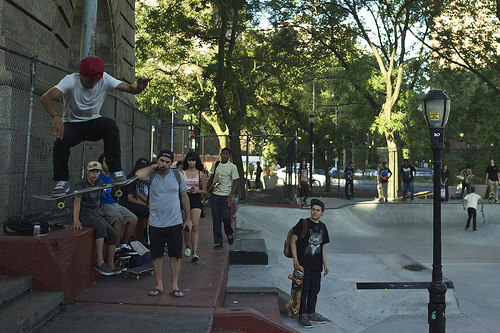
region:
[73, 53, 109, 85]
guy wearing red hat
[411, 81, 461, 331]
black street light pole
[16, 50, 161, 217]
guy jumping down steps on skateboard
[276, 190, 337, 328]
guy holding skate board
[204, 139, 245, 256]
guy walking down sidewalk with skateboard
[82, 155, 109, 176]
guy wearing tan hat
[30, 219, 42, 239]
can of soda pop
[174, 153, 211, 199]
girl wearing pink shirt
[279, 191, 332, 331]
guy wearing brown back pack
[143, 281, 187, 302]
guy wearing brown flip flops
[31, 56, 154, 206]
a skateboarder in air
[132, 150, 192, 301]
a man standing on sidewalk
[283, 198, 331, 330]
a man standing on sidewalk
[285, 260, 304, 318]
a standing skateboard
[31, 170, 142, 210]
a green and black skateboard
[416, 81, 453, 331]
a black street light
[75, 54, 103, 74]
a man's red hat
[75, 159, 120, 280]
a young man sitting on wall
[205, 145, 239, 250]
a pedestrian walking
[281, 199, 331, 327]
a young man with backpack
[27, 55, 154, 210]
A skateboarder in the air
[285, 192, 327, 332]
A man stands with a skateboarder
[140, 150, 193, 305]
A man with a gray t shirt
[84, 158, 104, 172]
The hat is yellow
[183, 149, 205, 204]
A girl is wearing a tank top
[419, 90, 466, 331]
The lamp post is black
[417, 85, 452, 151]
The lamp is off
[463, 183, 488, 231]
A person has a white shirt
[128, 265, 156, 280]
A skateboard on the ground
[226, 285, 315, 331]
The stairs are red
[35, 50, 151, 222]
a young man on a skateboard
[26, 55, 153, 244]
man and skateboard in the air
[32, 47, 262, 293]
group of people watching the skateboarder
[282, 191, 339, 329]
young boy with brown backpack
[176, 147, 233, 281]
a girl walking up a sidewalk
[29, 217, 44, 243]
a silver can of soda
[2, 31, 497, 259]
a chain link fence around the skatepark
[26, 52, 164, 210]
a young man doing a trick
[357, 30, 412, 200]
sun shining bright on the tree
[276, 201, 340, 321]
person in the skatepark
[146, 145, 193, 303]
person in the skatepark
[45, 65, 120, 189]
person in the skatepark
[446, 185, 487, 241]
person in the skatepark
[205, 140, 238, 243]
person in the skatepark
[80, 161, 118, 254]
person in the skatepark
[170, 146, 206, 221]
person in the skatepark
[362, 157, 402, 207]
person in the skatepark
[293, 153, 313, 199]
person in the skatepark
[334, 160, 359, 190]
person in the skatepark